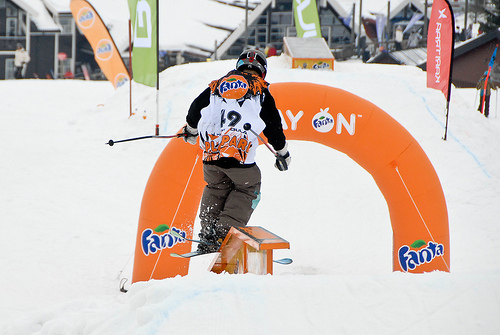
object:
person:
[172, 44, 295, 254]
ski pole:
[239, 121, 278, 159]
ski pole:
[103, 130, 193, 149]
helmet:
[232, 48, 270, 79]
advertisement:
[215, 73, 253, 102]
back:
[195, 69, 268, 170]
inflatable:
[125, 79, 456, 283]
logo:
[391, 238, 450, 276]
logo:
[134, 221, 191, 259]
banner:
[420, 0, 462, 106]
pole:
[438, 0, 462, 143]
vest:
[193, 70, 271, 169]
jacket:
[179, 65, 290, 173]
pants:
[189, 155, 268, 247]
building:
[199, 0, 402, 72]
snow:
[1, 47, 498, 334]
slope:
[92, 42, 500, 334]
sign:
[119, 0, 170, 94]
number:
[216, 107, 244, 129]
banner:
[63, 0, 141, 93]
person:
[7, 38, 33, 81]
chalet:
[0, 0, 141, 83]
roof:
[16, 0, 92, 34]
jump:
[278, 32, 338, 71]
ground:
[0, 49, 500, 335]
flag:
[287, 0, 326, 42]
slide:
[204, 221, 292, 274]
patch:
[248, 190, 262, 210]